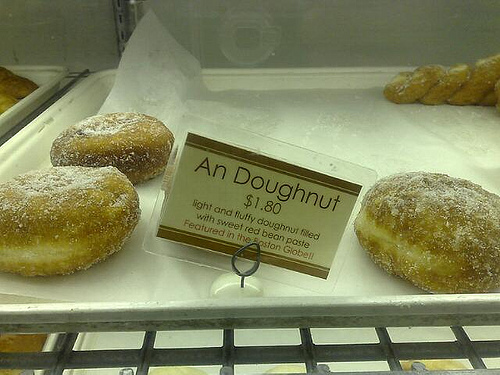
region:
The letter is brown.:
[191, 153, 213, 179]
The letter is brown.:
[211, 158, 229, 183]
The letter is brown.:
[228, 160, 253, 192]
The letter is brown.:
[248, 170, 265, 191]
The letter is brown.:
[262, 173, 279, 198]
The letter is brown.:
[276, 179, 294, 206]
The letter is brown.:
[289, 177, 308, 205]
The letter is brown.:
[303, 183, 320, 209]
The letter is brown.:
[315, 187, 334, 212]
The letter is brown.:
[331, 189, 343, 216]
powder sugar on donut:
[4, 176, 35, 211]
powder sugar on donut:
[36, 154, 61, 187]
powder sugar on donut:
[49, 180, 81, 211]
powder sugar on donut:
[67, 156, 94, 201]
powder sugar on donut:
[95, 163, 128, 205]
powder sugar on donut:
[77, 116, 102, 146]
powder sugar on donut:
[131, 99, 153, 137]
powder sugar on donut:
[397, 171, 420, 226]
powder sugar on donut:
[442, 177, 472, 227]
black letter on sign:
[192, 153, 212, 177]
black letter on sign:
[210, 160, 229, 182]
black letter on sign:
[229, 163, 251, 188]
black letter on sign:
[249, 173, 264, 193]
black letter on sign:
[262, 175, 279, 196]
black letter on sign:
[276, 181, 292, 206]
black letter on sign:
[291, 179, 305, 204]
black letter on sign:
[303, 187, 318, 209]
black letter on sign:
[318, 191, 331, 213]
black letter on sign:
[330, 193, 342, 214]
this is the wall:
[233, 5, 271, 31]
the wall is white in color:
[231, 10, 266, 40]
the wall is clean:
[248, 16, 296, 55]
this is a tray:
[292, 89, 358, 145]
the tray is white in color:
[122, 260, 154, 285]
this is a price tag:
[161, 115, 364, 287]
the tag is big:
[177, 112, 337, 307]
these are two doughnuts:
[20, 104, 130, 262]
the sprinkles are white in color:
[53, 172, 80, 192]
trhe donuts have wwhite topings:
[13, 97, 154, 245]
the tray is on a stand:
[128, 307, 323, 374]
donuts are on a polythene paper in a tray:
[68, 97, 200, 302]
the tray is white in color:
[252, 67, 391, 137]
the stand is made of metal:
[176, 332, 295, 374]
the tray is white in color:
[219, 58, 381, 153]